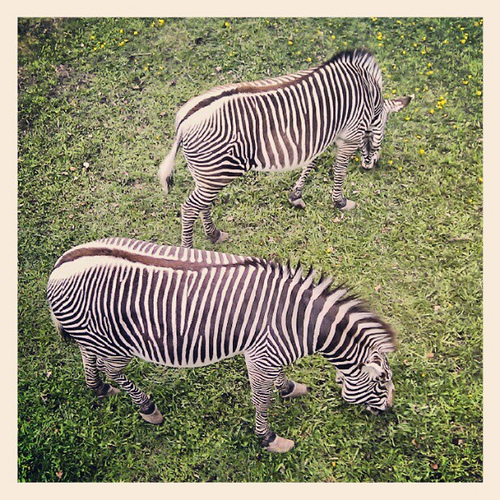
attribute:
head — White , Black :
[363, 85, 412, 178]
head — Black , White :
[318, 342, 400, 416]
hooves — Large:
[257, 421, 302, 460]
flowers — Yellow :
[298, 22, 481, 177]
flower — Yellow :
[286, 38, 294, 47]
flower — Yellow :
[303, 54, 313, 63]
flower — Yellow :
[372, 30, 383, 42]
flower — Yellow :
[413, 42, 417, 46]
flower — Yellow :
[401, 51, 405, 54]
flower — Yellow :
[460, 80, 469, 85]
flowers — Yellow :
[411, 31, 499, 136]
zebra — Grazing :
[140, 41, 444, 250]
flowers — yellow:
[77, 28, 142, 62]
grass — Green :
[26, 25, 158, 228]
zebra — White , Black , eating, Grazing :
[157, 49, 415, 251]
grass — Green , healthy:
[18, 16, 483, 483]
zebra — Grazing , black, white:
[47, 232, 396, 457]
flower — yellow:
[418, 148, 425, 155]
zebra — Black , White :
[25, 222, 422, 475]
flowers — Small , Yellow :
[435, 20, 472, 57]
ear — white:
[365, 357, 387, 379]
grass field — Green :
[18, 13, 481, 480]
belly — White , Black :
[111, 317, 244, 368]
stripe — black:
[47, 240, 286, 278]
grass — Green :
[19, 21, 476, 316]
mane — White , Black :
[262, 253, 393, 364]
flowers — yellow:
[395, 21, 472, 121]